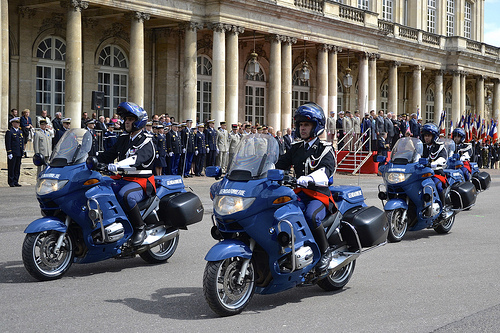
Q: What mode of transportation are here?
A: Motorcycles.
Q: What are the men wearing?
A: Uniforms.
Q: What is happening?
A: A parade.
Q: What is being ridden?
A: Motorcycles.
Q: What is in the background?
A: A building.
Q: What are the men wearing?
A: Uniforms.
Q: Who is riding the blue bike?
A: A man.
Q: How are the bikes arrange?
A: In line.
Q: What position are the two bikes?
A: Side by side.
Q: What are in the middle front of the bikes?
A: Headlights.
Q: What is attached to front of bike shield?
A: Shield support.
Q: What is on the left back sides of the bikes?
A: Two black cases.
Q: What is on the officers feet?
A: Black boots.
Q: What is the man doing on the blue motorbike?
A: Riding the bike.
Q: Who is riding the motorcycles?
A: The people.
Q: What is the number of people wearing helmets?
A: Four.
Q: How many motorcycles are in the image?
A: Four.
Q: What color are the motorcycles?
A: Blue.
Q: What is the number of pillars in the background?
A: Eighteen.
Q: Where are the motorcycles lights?
A: In the front.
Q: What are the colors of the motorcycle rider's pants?
A: Black and blue.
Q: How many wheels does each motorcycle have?
A: Two.